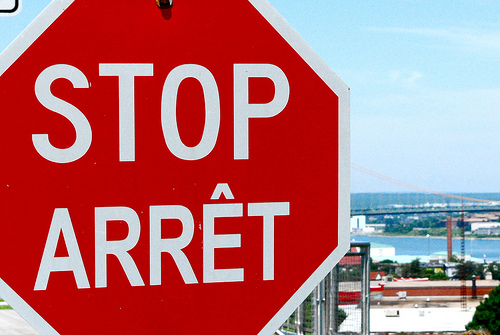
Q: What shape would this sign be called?
A: Octagon.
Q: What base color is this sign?
A: Red.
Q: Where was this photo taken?
A: Near water.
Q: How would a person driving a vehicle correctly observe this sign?
A: By stopping.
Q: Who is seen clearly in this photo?
A: No One.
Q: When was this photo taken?
A: Daytime.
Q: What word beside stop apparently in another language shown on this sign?
A: Arret.